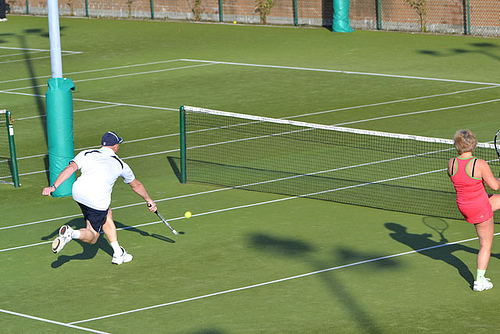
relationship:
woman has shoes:
[433, 123, 491, 287] [473, 278, 492, 295]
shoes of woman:
[473, 278, 492, 295] [433, 123, 491, 287]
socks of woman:
[472, 269, 487, 278] [433, 123, 491, 287]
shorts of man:
[80, 205, 112, 221] [42, 111, 152, 261]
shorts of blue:
[80, 205, 112, 221] [102, 215, 119, 225]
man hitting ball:
[42, 111, 152, 261] [181, 203, 194, 228]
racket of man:
[150, 204, 186, 237] [42, 111, 152, 261]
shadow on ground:
[18, 29, 45, 46] [103, 14, 143, 36]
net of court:
[212, 120, 314, 171] [258, 70, 341, 97]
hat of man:
[88, 127, 123, 146] [42, 111, 152, 261]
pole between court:
[167, 111, 186, 189] [258, 70, 341, 97]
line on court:
[132, 49, 163, 77] [258, 70, 341, 97]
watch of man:
[41, 177, 57, 190] [42, 111, 152, 261]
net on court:
[212, 120, 314, 171] [258, 70, 341, 97]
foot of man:
[55, 226, 68, 262] [42, 111, 152, 261]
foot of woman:
[55, 226, 68, 262] [433, 123, 491, 287]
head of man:
[98, 138, 120, 152] [42, 111, 152, 261]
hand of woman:
[144, 197, 157, 213] [433, 123, 491, 287]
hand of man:
[144, 197, 157, 213] [42, 111, 152, 261]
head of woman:
[98, 138, 120, 152] [433, 123, 491, 287]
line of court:
[132, 49, 163, 77] [258, 70, 341, 97]